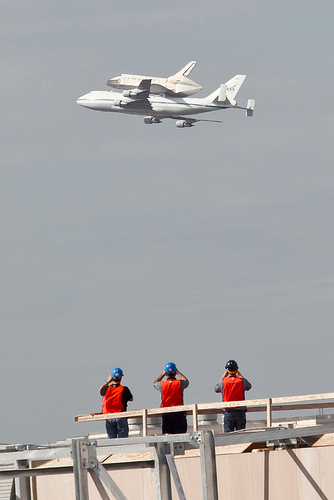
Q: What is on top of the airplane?
A: A space shuttle.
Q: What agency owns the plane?
A: NASA.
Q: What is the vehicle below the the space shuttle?
A: An airplane.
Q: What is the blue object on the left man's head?
A: A helmet.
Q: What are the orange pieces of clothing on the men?
A: Vests.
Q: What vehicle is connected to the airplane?
A: A space shuttle.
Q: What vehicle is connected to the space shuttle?
A: An airplane.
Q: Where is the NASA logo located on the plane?
A: On the tail.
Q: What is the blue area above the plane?
A: The sky.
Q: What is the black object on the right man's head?
A: A helmet.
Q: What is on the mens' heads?
A: Helmets.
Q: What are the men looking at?
A: Airplane.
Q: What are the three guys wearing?
A: Orange vests.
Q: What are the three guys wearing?
A: Orange vest.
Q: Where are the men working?
A: In the outside.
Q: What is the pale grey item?
A: Sky.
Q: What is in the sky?
A: Plane.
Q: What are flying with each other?
A: Two airplanes.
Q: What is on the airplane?
A: Shuttle.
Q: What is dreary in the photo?
A: Sky.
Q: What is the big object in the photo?
A: Airplane.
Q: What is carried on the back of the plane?
A: Rocket ship.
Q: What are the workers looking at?
A: Planes.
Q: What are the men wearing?
A: Hard hat.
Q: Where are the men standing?
A: On a walkway?.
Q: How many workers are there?
A: Three.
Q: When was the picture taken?
A: Daytime.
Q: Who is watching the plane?
A: Workers.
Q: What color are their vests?
A: Red.